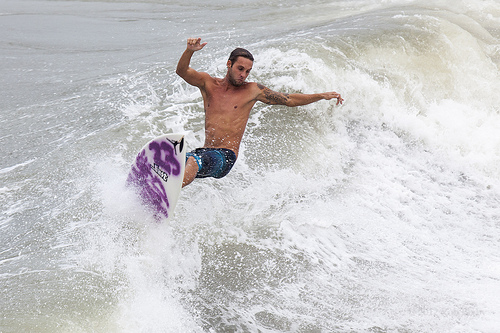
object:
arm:
[255, 81, 347, 108]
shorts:
[183, 147, 238, 181]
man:
[174, 36, 345, 187]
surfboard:
[125, 130, 186, 224]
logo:
[165, 135, 185, 156]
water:
[0, 0, 500, 332]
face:
[232, 56, 254, 87]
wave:
[103, 46, 500, 331]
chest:
[201, 85, 252, 148]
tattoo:
[256, 82, 291, 107]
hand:
[184, 35, 207, 54]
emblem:
[149, 162, 169, 183]